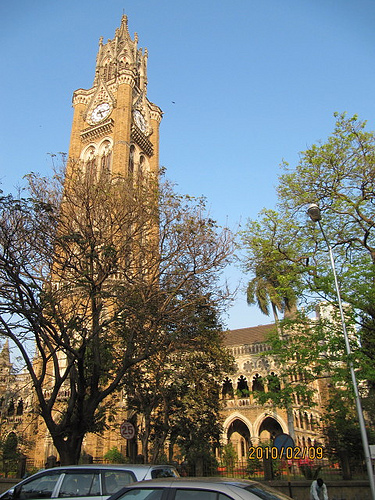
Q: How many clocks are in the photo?
A: Two.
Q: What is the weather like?
A: Sunny.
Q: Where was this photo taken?
A: Boston.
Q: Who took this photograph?
A: A tourist.